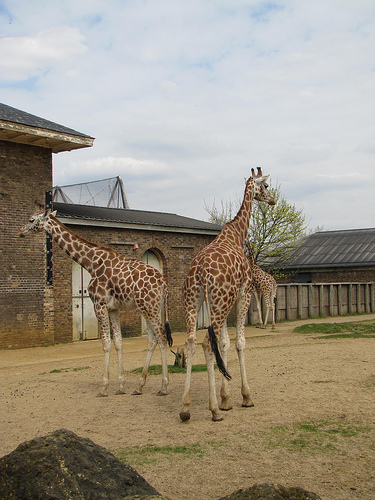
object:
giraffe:
[15, 204, 174, 399]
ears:
[42, 208, 52, 219]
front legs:
[93, 305, 113, 400]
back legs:
[137, 302, 170, 397]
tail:
[164, 287, 174, 348]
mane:
[49, 213, 117, 253]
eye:
[28, 217, 36, 223]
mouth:
[16, 232, 25, 239]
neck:
[45, 217, 94, 274]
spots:
[114, 284, 121, 295]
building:
[54, 201, 237, 345]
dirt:
[0, 315, 375, 500]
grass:
[292, 321, 375, 340]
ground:
[0, 314, 373, 498]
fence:
[248, 282, 374, 326]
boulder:
[0, 426, 173, 500]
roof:
[54, 202, 225, 231]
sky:
[0, 0, 374, 231]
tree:
[254, 204, 292, 262]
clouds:
[0, 33, 59, 86]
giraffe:
[178, 165, 278, 423]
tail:
[202, 273, 234, 384]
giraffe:
[244, 234, 279, 331]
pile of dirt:
[224, 482, 316, 500]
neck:
[247, 245, 255, 265]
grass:
[282, 414, 335, 452]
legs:
[178, 294, 202, 423]